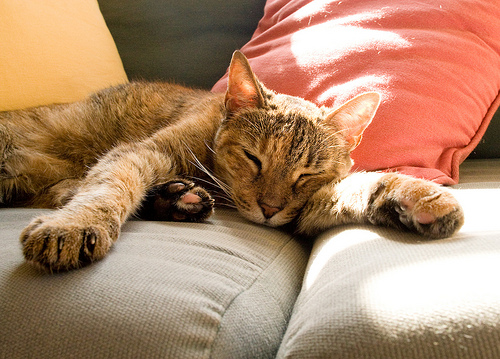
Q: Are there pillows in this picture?
A: Yes, there is a pillow.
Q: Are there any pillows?
A: Yes, there is a pillow.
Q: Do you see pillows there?
A: Yes, there is a pillow.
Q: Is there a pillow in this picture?
A: Yes, there is a pillow.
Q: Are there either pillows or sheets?
A: Yes, there is a pillow.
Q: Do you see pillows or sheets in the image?
A: Yes, there is a pillow.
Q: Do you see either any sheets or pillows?
A: Yes, there is a pillow.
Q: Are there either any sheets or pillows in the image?
A: Yes, there is a pillow.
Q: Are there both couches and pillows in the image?
A: Yes, there are both a pillow and a couch.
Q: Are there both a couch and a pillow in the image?
A: Yes, there are both a pillow and a couch.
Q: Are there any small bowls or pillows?
A: Yes, there is a small pillow.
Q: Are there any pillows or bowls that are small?
A: Yes, the pillow is small.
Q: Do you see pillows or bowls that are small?
A: Yes, the pillow is small.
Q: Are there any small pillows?
A: Yes, there is a small pillow.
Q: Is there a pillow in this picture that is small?
A: Yes, there is a pillow that is small.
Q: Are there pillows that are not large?
A: Yes, there is a small pillow.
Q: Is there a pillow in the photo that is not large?
A: Yes, there is a small pillow.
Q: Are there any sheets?
A: No, there are no sheets.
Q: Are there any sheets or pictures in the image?
A: No, there are no sheets or pictures.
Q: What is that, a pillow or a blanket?
A: That is a pillow.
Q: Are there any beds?
A: No, there are no beds.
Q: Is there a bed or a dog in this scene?
A: No, there are no beds or dogs.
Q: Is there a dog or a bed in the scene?
A: No, there are no beds or dogs.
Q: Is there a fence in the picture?
A: No, there are no fences.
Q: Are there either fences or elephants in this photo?
A: No, there are no fences or elephants.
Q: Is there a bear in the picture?
A: No, there are no bears.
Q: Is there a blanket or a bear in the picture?
A: No, there are no bears or blankets.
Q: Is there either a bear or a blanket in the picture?
A: No, there are no bears or blankets.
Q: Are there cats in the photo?
A: Yes, there is a cat.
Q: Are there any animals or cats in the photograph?
A: Yes, there is a cat.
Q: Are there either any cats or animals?
A: Yes, there is a cat.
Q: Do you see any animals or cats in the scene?
A: Yes, there is a cat.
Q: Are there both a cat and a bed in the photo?
A: No, there is a cat but no beds.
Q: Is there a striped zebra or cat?
A: Yes, there is a striped cat.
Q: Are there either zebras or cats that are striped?
A: Yes, the cat is striped.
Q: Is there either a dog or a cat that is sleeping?
A: Yes, the cat is sleeping.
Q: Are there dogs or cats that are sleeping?
A: Yes, the cat is sleeping.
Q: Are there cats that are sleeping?
A: Yes, there is a cat that is sleeping.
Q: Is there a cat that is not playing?
A: Yes, there is a cat that is sleeping.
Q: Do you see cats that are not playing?
A: Yes, there is a cat that is sleeping .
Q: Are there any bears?
A: No, there are no bears.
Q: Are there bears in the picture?
A: No, there are no bears.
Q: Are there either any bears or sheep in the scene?
A: No, there are no bears or sheep.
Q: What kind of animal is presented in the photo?
A: The animal is a cat.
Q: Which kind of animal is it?
A: The animal is a cat.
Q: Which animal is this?
A: That is a cat.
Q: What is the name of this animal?
A: That is a cat.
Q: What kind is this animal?
A: That is a cat.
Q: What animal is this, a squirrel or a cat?
A: That is a cat.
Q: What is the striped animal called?
A: The animal is a cat.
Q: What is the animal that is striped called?
A: The animal is a cat.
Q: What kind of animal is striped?
A: The animal is a cat.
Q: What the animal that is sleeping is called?
A: The animal is a cat.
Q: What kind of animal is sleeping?
A: The animal is a cat.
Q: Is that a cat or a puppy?
A: That is a cat.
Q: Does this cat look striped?
A: Yes, the cat is striped.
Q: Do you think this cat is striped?
A: Yes, the cat is striped.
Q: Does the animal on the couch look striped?
A: Yes, the cat is striped.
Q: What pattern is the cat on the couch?
A: The cat is striped.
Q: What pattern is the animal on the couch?
A: The cat is striped.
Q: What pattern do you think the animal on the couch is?
A: The cat is striped.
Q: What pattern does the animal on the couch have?
A: The cat has striped pattern.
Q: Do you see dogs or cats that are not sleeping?
A: No, there is a cat but it is sleeping.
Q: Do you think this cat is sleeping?
A: Yes, the cat is sleeping.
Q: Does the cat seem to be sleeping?
A: Yes, the cat is sleeping.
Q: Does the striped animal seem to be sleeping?
A: Yes, the cat is sleeping.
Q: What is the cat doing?
A: The cat is sleeping.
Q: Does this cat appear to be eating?
A: No, the cat is sleeping.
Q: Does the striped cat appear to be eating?
A: No, the cat is sleeping.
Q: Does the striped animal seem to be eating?
A: No, the cat is sleeping.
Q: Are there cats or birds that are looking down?
A: No, there is a cat but it is sleeping.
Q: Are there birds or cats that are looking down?
A: No, there is a cat but it is sleeping.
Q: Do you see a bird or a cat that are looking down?
A: No, there is a cat but it is sleeping.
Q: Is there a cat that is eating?
A: No, there is a cat but it is sleeping.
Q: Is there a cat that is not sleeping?
A: No, there is a cat but it is sleeping.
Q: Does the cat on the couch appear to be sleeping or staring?
A: The cat is sleeping.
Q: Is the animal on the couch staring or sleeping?
A: The cat is sleeping.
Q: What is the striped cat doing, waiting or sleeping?
A: The cat is sleeping.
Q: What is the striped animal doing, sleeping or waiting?
A: The cat is sleeping.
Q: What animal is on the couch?
A: The animal is a cat.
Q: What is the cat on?
A: The cat is on the couch.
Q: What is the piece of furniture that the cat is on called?
A: The piece of furniture is a couch.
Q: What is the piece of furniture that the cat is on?
A: The piece of furniture is a couch.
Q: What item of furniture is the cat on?
A: The cat is on the couch.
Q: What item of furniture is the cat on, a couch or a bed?
A: The cat is on a couch.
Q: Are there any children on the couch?
A: No, there is a cat on the couch.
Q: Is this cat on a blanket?
A: No, the cat is on the couch.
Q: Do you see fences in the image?
A: No, there are no fences.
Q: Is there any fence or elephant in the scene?
A: No, there are no fences or elephants.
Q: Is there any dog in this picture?
A: No, there are no dogs.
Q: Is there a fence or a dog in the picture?
A: No, there are no dogs or fences.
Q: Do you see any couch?
A: Yes, there is a couch.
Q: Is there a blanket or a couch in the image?
A: Yes, there is a couch.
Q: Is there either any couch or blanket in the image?
A: Yes, there is a couch.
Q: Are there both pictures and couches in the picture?
A: No, there is a couch but no pictures.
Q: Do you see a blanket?
A: No, there are no blankets.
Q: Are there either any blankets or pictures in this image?
A: No, there are no blankets or pictures.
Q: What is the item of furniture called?
A: The piece of furniture is a couch.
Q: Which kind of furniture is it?
A: The piece of furniture is a couch.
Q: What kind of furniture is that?
A: This is a couch.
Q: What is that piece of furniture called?
A: This is a couch.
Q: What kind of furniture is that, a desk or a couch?
A: This is a couch.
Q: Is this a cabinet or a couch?
A: This is a couch.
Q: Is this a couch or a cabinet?
A: This is a couch.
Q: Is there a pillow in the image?
A: Yes, there is a pillow.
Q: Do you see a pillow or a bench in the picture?
A: Yes, there is a pillow.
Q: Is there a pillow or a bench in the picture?
A: Yes, there is a pillow.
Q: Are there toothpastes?
A: No, there are no toothpastes.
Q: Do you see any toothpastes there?
A: No, there are no toothpastes.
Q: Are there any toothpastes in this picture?
A: No, there are no toothpastes.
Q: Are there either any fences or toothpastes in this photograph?
A: No, there are no toothpastes or fences.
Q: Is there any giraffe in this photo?
A: No, there are no giraffes.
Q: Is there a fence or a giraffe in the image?
A: No, there are no giraffes or fences.